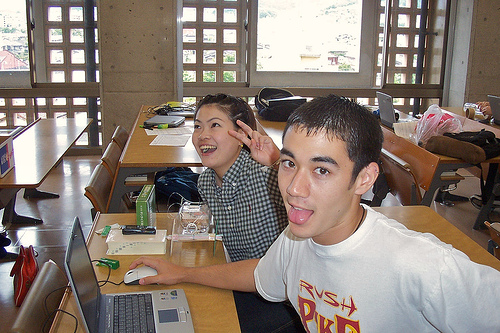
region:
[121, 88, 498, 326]
two people setting at a desk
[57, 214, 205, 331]
a laptop is sitting on a desk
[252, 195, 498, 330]
the man's t-shirt is white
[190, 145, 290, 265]
she is wearing a checkered shirt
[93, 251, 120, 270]
a green pack of gum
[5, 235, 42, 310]
a red bag sitting on the floor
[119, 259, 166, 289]
the mouse is white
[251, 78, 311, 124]
a black backpack and notebook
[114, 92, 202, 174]
the desk is brown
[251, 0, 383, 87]
a window in the wall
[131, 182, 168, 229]
green and white box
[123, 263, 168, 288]
white computer mouse with black spot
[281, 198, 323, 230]
boy's orange tongue hanging out of his mouth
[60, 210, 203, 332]
tan laptop with black keys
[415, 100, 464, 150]
white plastic bag with pink clothing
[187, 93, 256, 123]
girl's braided black hair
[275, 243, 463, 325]
man's white tee shirt with red marking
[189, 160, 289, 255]
girl's blue and white checkered plait shirt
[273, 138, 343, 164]
man's bushy black eyebrows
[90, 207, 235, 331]
tan shiny wood desk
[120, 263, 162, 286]
Computer mouse in hand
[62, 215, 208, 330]
Laptop computer on desk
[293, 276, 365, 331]
Words printed on t-shirt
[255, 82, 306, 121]
Backpack on desk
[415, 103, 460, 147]
Plastic bag of stuff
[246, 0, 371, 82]
Window letting light in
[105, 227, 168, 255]
Thick book resting on desk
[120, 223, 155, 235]
Cell phone on book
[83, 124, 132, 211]
Chairs pushed into desk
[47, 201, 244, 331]
Desk being used for studies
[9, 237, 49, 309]
a red bag on the floor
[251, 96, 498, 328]
a boy in a white tshirt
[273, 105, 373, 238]
young man with tongue sticking out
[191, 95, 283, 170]
a young girl throwing up the peace sign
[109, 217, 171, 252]
a cell phone sitting on a book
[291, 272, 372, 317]
the word rush in red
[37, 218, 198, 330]
a mouse hooked up to a laptop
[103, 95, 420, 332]
two people sitting at a desk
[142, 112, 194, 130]
a closed laptop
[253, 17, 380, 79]
sun shining bright in the window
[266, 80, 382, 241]
young man sticking out tongue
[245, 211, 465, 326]
white T-shirt with red and yellow words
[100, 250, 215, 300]
hand holding computer mouse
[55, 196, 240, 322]
open laptop on long table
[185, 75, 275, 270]
woman with two raised fingers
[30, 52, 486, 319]
classroom with two students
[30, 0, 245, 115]
grid pattern on side of building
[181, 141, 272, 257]
young woman wearing plaid shirt with collar buttons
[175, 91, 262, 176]
woman looking upward with open mouth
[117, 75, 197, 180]
closed laptops and papers on table